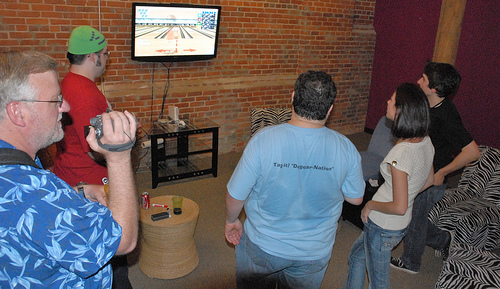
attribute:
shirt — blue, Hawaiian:
[0, 133, 123, 285]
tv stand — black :
[138, 117, 218, 188]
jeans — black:
[401, 180, 452, 269]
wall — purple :
[365, 1, 499, 149]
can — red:
[113, 173, 205, 238]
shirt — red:
[38, 70, 113, 183]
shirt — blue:
[241, 123, 364, 255]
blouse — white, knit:
[370, 138, 437, 230]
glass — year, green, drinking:
[169, 197, 185, 212]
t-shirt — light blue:
[226, 120, 364, 260]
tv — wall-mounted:
[129, 3, 222, 63]